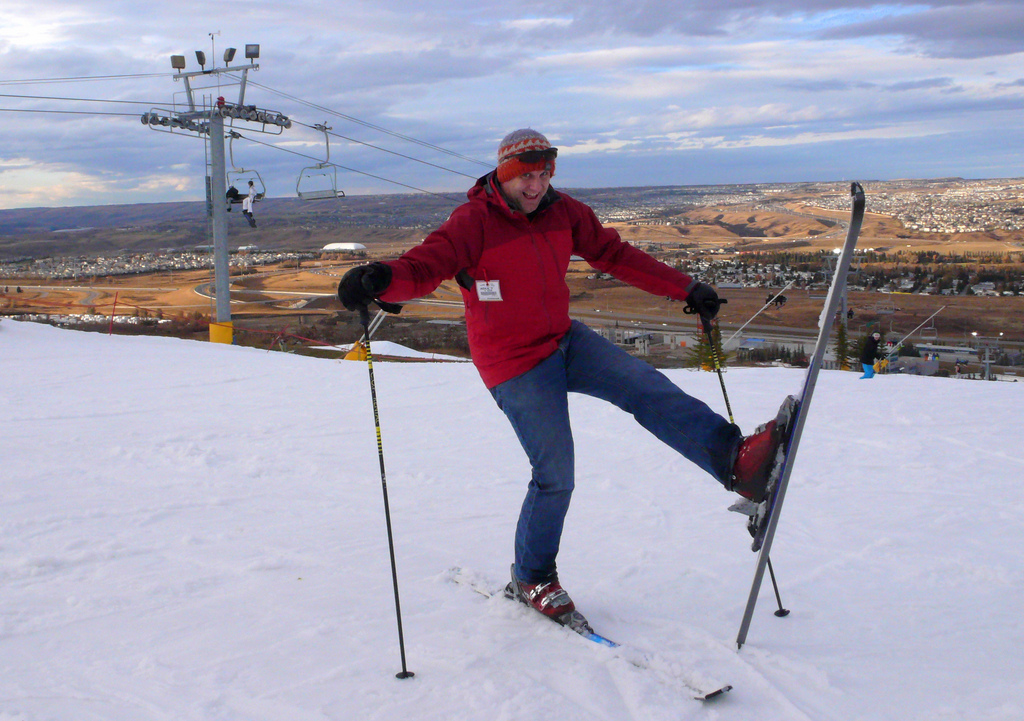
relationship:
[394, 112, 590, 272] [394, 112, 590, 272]
head of man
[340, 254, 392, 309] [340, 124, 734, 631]
glove of man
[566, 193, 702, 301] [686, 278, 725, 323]
arm of man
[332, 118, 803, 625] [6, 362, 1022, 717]
man doing a trick in snow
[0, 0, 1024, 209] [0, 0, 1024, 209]
clouds in clouds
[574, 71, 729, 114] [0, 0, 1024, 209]
clouds in clouds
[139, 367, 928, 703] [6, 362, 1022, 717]
foot prints on snow